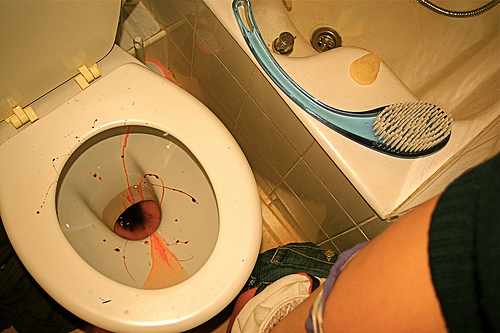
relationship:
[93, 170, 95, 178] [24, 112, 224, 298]
blood in toilet bowl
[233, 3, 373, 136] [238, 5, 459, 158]
handle on brush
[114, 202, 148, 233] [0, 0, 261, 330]
blood is in toilet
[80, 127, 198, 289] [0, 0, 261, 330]
blood is in toilet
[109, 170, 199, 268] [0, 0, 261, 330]
blood is in toilet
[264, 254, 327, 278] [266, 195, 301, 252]
jeans on floor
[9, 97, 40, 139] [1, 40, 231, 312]
hinge on toilet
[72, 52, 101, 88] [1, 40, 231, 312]
hinge on toilet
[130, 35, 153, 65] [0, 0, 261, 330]
handle at back of toilet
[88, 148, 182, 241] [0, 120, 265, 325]
red in toilet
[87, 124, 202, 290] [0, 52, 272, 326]
orange in toilet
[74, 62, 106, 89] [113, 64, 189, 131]
white hinge on toilet seat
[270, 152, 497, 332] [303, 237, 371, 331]
person wearing underwear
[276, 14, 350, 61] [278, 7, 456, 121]
faucet on tub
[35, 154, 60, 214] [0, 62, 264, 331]
blood on toilet seat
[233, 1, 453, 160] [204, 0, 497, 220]
scrub brush on shelf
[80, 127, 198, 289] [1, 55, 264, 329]
blood in toilet bowl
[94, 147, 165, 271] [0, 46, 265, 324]
blood in bowl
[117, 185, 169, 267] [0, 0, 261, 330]
blood in toilet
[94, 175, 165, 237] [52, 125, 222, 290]
blood in toilet bowl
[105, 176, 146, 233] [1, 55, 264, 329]
blood in toilet bowl